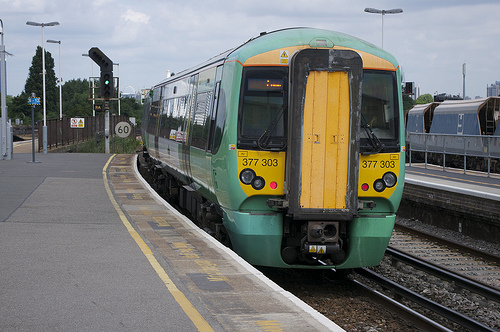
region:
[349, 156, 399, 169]
number on train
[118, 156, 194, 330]
yellow line on platform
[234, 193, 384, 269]
front of train is green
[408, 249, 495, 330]
three tracks on ground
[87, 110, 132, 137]
number 60 on fence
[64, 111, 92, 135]
sign on fence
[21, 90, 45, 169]
pole on the sidewalk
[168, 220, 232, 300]
yellow words on platform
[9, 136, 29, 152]
street along fence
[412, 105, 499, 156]
silver train on other side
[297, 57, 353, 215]
The front is yellow.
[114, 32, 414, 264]
The train is green and yellow.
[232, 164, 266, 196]
The light is off.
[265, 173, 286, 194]
The light is red.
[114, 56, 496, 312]
The train is on the track.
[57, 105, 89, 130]
The sign is white.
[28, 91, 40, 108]
The sign is blue.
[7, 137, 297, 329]
The sidewalk is gray.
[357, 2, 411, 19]
The light is off.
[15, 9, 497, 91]
The sky is overcast.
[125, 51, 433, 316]
train at the train station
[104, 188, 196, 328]
a yellow painted line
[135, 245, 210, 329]
a yellow painted line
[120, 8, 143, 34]
clouds in the sky.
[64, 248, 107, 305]
crack in the concrete.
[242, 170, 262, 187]
lights on the train.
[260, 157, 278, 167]
numbers on the train.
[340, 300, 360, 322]
pebbles near the tracks.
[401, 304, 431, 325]
track made of steel.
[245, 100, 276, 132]
window on the train.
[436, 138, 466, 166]
railing on the platform.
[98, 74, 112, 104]
traffic light near platform.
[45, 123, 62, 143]
fence near the platform.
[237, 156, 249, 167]
The number is black.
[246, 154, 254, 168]
The number is black.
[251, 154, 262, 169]
The number is black.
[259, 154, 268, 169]
The number is black.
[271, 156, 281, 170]
The number is black.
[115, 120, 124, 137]
The number is black.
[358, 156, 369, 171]
The number is black.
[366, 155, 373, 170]
The number is black.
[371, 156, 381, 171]
The number is black.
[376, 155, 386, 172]
The number is black.